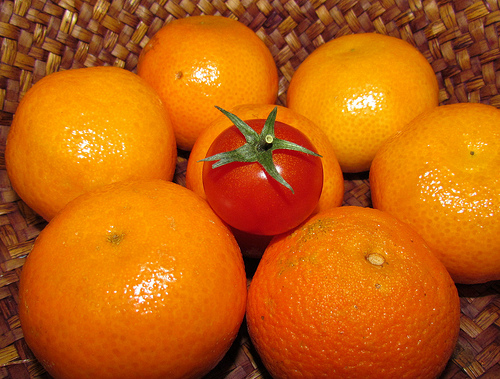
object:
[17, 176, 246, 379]
fruits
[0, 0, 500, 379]
basket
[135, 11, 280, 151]
oranges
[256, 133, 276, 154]
stem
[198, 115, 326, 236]
tomato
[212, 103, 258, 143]
leaf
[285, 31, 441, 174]
orange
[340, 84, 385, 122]
glare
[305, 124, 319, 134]
spot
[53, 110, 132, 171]
shine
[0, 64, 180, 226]
orange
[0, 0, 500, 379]
wicker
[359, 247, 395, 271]
hole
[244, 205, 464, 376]
orange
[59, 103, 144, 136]
grooves